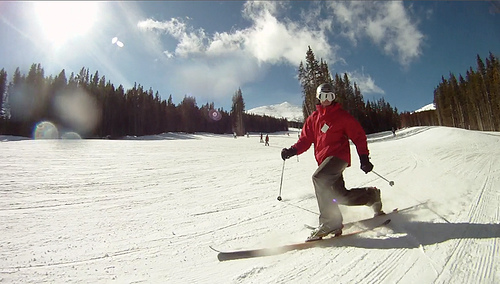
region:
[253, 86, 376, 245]
person skiing on snowy moutain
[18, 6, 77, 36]
white clouds in blue sky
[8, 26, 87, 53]
white clouds in blue sky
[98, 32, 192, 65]
white clouds in blue sky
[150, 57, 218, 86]
white clouds in blue sky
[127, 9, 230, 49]
white clouds in blue sky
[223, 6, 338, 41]
white clouds in blue sky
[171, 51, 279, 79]
white clouds in blue sky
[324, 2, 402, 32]
white clouds in blue sky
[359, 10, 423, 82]
white clouds in blue sky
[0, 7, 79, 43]
white clouds against blue sky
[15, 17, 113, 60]
white clouds against blue sky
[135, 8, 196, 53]
white clouds against blue sky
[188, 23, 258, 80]
white clouds against blue sky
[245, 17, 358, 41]
white clouds against blue sky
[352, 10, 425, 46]
white clouds against blue sky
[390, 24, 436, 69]
white clouds against blue sky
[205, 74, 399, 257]
person cross country skiing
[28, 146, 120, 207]
white snow on hill side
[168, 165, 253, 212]
white snow on hill side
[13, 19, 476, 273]
this person is skiiing down the mountain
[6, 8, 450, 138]
a sunny day for skiing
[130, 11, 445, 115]
a few clouds in the above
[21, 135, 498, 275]
smooth flat snow for skiing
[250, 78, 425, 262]
this skier is moving quickly down the mountain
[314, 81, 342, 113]
this man wearing a goggles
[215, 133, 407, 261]
this skier is using correct form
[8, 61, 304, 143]
trees in the scene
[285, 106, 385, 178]
the skier is wearing a red jacket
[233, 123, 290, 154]
people in the background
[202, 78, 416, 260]
A skiier in a red coat.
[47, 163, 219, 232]
White snow which has been skiied on.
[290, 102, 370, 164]
A red, puffy skiing coat.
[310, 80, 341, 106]
A skiing helmet and reflective goggles.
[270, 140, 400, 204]
A pair of skiing poles.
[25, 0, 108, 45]
The winter sun in the sky.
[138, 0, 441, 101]
Clouds in a blue sky.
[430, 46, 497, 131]
Green and brown pine trees.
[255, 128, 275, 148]
Distant skiiers.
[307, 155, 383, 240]
Brown ski pants and white boots.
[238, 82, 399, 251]
person snow skiing on mountain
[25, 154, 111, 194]
white snow on mountain side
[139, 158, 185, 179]
white snow on mountain side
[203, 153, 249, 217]
white snow on mountain side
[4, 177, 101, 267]
white snow on mountain side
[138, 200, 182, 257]
white snow on mountain side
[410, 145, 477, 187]
white snow on mountain side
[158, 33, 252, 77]
white clouds in blue sky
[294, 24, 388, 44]
white clouds in blue sky